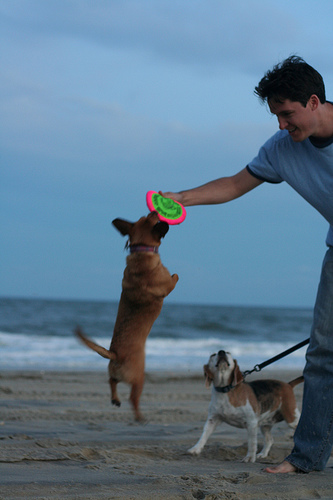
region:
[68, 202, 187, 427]
small dog, it jumps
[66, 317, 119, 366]
small tail, it wags [with great joy]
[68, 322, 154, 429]
small dog, small legs, tail longer than either or both of them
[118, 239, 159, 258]
small dog, tartan looking collar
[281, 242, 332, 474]
guy's pants, denim jeans, scrape ground: his mom would -yell-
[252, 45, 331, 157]
guy, mid-thirties, not bad looking, unfortunately resembles 'turkerworker's unfortunate, not to mention wretched, second husband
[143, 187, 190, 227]
smallish frisbee, hot pink rim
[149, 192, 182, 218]
fluoro green frisbee in the main, w/ black printing obscured by small subject dog's motion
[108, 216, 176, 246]
small dog, the black ears, they flap back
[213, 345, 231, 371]
the smile on the semi-joyous face of a friendly beagle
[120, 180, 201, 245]
frisbee is neon green and pink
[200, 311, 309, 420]
dog is on leash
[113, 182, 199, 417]
dog jumping for frisbee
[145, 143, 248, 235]
man holding the frisbee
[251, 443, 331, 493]
man is barefoot in the sand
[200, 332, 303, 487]
dog is brown and white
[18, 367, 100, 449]
tire tracks in the sand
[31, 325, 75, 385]
water coming to shore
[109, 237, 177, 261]
dog has blue and red collar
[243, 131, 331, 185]
man's shirt is blue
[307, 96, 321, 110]
ear on the man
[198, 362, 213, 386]
ear on the dog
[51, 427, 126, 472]
sand on the beach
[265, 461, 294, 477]
man's foot on beach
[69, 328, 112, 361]
tale of brown dog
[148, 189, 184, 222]
pink and green frisbee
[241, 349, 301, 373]
part of dog leash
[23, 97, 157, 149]
part of the sky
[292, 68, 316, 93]
hair on the man's head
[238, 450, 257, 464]
a paw on dog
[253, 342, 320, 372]
black leash attached to dog on right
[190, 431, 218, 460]
white paw located on beagle's front right paw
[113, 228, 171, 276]
red collar on jumping dog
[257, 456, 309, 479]
bare foot of man on beach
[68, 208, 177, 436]
jumping redish brown dog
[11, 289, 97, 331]
dark blue ocean water in distance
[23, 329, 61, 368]
white foam near front of water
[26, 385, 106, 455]
tire prints in sand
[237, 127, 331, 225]
light blue tshirt with dark blue collar and sleeves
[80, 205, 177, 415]
a small brown dog jumping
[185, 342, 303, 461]
a small brown and white dog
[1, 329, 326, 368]
white crashing waves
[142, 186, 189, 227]
a neon pink and green flying saucer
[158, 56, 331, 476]
a man standing on beach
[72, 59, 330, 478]
a man playing frisbee with dog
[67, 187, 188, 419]
dog with frisbee in mouth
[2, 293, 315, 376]
a large body of water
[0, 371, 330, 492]
a wet sandy beach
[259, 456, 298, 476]
a man's bare foot